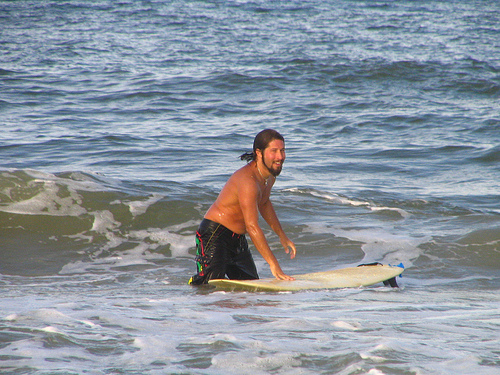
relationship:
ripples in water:
[1, 4, 499, 182] [2, 2, 498, 370]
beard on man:
[262, 156, 284, 177] [194, 129, 296, 284]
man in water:
[194, 129, 296, 284] [2, 2, 498, 370]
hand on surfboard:
[262, 261, 296, 283] [207, 251, 407, 298]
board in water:
[208, 265, 405, 292] [2, 2, 498, 370]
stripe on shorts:
[191, 227, 207, 276] [186, 217, 257, 284]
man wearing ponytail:
[194, 129, 296, 284] [239, 149, 255, 162]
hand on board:
[270, 263, 296, 280] [204, 263, 405, 289]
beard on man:
[268, 165, 283, 174] [194, 129, 296, 284]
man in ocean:
[194, 129, 296, 284] [2, 4, 498, 373]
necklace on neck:
[253, 161, 273, 186] [247, 156, 276, 186]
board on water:
[208, 265, 405, 292] [2, 2, 498, 370]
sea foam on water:
[8, 164, 498, 374] [2, 2, 498, 370]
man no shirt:
[194, 129, 296, 284] [209, 160, 272, 241]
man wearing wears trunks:
[190, 127, 305, 283] [186, 216, 261, 286]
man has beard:
[194, 129, 296, 284] [262, 152, 282, 177]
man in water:
[183, 123, 301, 293] [2, 2, 498, 370]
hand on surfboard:
[270, 263, 296, 280] [199, 253, 409, 297]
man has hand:
[194, 129, 296, 284] [270, 263, 296, 280]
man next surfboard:
[194, 129, 296, 284] [207, 259, 406, 300]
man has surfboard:
[183, 123, 301, 293] [204, 258, 411, 296]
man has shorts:
[194, 129, 296, 284] [188, 217, 260, 285]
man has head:
[194, 129, 296, 284] [253, 127, 288, 177]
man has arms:
[183, 123, 301, 293] [243, 178, 308, 290]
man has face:
[194, 129, 296, 284] [257, 140, 286, 172]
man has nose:
[183, 123, 301, 293] [274, 149, 282, 162]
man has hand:
[194, 129, 296, 284] [279, 237, 296, 261]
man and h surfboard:
[194, 129, 296, 284] [194, 255, 410, 294]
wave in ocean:
[1, 158, 497, 290] [2, 4, 498, 373]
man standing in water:
[194, 129, 296, 284] [2, 2, 498, 370]